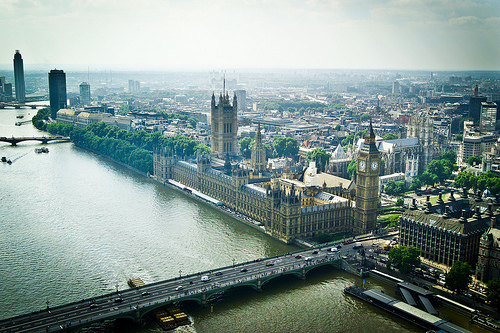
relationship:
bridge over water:
[2, 245, 346, 330] [0, 107, 428, 330]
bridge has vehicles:
[2, 245, 346, 330] [186, 270, 227, 286]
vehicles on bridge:
[186, 270, 227, 286] [2, 245, 346, 330]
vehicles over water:
[186, 270, 227, 286] [0, 107, 428, 330]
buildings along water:
[388, 205, 500, 286] [0, 107, 428, 330]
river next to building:
[134, 264, 430, 333] [13, 50, 25, 103]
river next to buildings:
[134, 264, 430, 333] [388, 205, 500, 286]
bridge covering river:
[2, 245, 346, 330] [134, 264, 430, 333]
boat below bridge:
[129, 277, 191, 330] [2, 245, 346, 330]